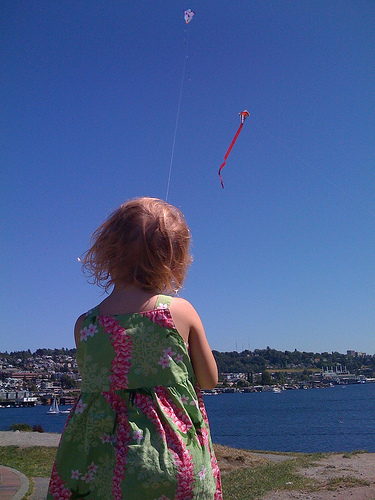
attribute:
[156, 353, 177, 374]
flower — white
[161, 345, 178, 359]
flower — white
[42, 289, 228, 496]
dress — floral print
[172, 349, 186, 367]
flower — white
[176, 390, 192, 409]
flower — white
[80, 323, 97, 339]
flower — white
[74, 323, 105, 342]
flower — white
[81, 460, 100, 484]
flower — white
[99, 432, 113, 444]
flower — white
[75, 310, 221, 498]
dress — pink, green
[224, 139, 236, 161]
tail — red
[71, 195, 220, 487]
girl — little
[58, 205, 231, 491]
girl — little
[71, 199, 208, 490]
girl — little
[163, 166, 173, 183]
string — white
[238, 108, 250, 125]
kite — red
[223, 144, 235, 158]
tail — red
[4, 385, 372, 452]
water — dark blue, calm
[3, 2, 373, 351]
sky — clear, blue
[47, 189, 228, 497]
girl — floral print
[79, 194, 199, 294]
hair — blonde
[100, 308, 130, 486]
flowers — pink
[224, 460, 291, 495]
grass — short, green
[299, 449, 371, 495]
dirt — brown